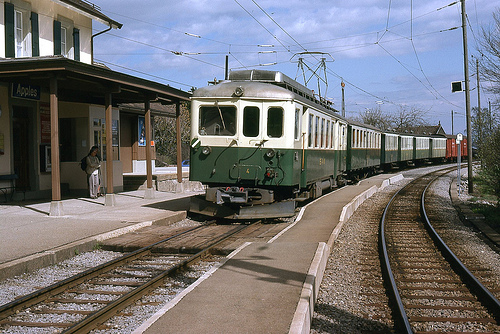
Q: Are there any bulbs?
A: No, there are no bulbs.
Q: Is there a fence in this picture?
A: No, there are no fences.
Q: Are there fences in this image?
A: No, there are no fences.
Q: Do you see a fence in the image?
A: No, there are no fences.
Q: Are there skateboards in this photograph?
A: No, there are no skateboards.